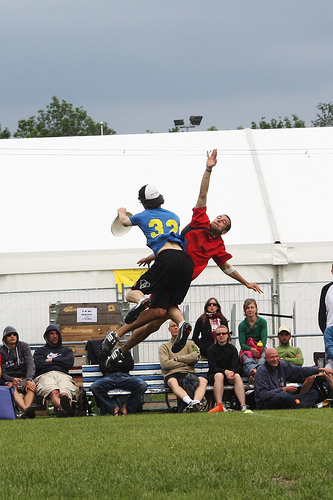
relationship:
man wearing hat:
[118, 184, 191, 353] [138, 184, 163, 209]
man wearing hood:
[3, 328, 36, 417] [3, 327, 20, 349]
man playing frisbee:
[118, 184, 191, 353] [111, 210, 133, 238]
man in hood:
[3, 328, 36, 417] [3, 327, 20, 349]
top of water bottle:
[254, 339, 263, 345] [256, 340, 263, 358]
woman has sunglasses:
[192, 296, 229, 357] [206, 301, 218, 306]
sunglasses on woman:
[206, 301, 218, 306] [192, 296, 229, 357]